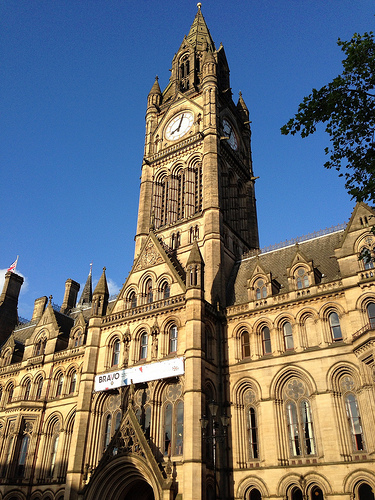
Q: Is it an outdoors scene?
A: Yes, it is outdoors.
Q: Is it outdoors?
A: Yes, it is outdoors.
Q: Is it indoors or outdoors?
A: It is outdoors.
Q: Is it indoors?
A: No, it is outdoors.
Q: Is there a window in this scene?
A: Yes, there are windows.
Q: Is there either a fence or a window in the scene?
A: Yes, there are windows.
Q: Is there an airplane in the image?
A: No, there are no airplanes.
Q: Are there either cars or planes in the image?
A: No, there are no planes or cars.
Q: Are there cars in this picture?
A: No, there are no cars.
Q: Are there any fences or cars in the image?
A: No, there are no cars or fences.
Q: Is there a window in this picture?
A: Yes, there is a window.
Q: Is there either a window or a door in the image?
A: Yes, there is a window.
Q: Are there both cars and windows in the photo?
A: No, there is a window but no cars.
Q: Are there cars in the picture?
A: No, there are no cars.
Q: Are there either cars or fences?
A: No, there are no cars or fences.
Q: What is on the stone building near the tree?
A: The sign is on the building.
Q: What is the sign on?
A: The sign is on the building.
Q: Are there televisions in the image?
A: No, there are no televisions.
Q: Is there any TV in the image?
A: No, there are no televisions.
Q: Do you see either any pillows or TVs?
A: No, there are no TVs or pillows.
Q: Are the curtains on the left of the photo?
A: No, the curtains are on the right of the image.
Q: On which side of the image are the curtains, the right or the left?
A: The curtains are on the right of the image.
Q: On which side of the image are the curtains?
A: The curtains are on the right of the image.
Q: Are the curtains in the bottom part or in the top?
A: The curtains are in the bottom of the image.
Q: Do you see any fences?
A: No, there are no fences.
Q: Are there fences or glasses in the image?
A: No, there are no fences or glasses.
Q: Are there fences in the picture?
A: No, there are no fences.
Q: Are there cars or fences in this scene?
A: No, there are no fences or cars.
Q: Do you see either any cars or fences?
A: No, there are no fences or cars.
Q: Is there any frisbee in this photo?
A: No, there are no frisbees.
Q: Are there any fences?
A: No, there are no fences.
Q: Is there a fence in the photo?
A: No, there are no fences.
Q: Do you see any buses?
A: No, there are no buses.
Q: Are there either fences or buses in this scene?
A: No, there are no buses or fences.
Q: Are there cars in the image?
A: No, there are no cars.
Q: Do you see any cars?
A: No, there are no cars.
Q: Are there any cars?
A: No, there are no cars.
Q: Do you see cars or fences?
A: No, there are no cars or fences.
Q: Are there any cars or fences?
A: No, there are no cars or fences.